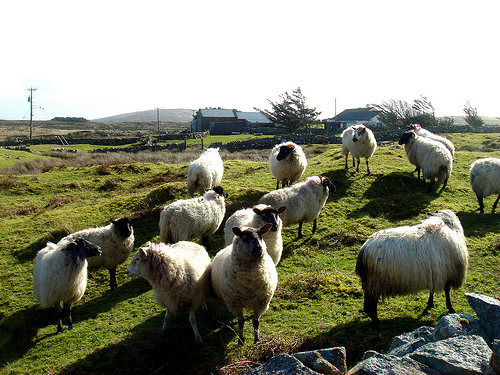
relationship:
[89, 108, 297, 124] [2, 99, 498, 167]
mountain in distance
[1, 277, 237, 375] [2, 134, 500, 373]
shadows on field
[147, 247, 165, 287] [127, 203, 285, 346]
neck of sheep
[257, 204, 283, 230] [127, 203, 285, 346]
head of sheep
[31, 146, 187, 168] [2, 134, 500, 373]
thicket on field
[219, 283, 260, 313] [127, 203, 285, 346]
stomach of sheep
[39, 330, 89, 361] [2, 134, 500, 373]
grass on field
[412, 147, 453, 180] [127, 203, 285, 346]
edge of sheep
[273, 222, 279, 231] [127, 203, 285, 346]
nose of sheep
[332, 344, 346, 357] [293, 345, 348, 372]
edge of rocks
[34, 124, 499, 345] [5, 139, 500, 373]
sheep in field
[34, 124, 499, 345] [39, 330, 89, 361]
sheep in grass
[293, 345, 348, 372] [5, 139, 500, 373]
rocks in field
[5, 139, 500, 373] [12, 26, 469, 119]
photo of day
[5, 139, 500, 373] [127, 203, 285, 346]
field of sheep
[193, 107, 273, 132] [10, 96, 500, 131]
building in background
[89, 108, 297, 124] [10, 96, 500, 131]
mountain in background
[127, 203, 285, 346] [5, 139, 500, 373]
sheep in field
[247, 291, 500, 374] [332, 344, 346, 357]
rocks on edge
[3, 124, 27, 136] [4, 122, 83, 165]
dirt in grass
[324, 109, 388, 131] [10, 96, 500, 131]
house in background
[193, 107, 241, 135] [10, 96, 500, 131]
building in background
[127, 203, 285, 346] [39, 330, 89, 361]
sheep on grass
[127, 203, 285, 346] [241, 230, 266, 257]
sheep has face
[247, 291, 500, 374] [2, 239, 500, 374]
rocks in foreground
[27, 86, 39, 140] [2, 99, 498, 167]
pole in distance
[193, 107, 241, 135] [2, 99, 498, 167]
building in distance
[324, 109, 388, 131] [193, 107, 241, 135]
house by building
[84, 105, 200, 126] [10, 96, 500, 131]
mountain in background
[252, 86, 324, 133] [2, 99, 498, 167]
tree in distance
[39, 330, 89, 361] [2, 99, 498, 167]
grass in distance